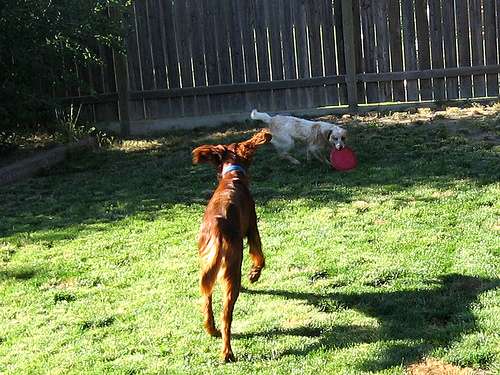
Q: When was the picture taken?
A: During the day.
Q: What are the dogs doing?
A: Playing.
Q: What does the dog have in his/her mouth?
A: A frisbee.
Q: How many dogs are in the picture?
A: Two.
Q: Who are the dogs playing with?
A: Each other.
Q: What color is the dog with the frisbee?
A: White.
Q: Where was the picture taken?
A: In a backyard.